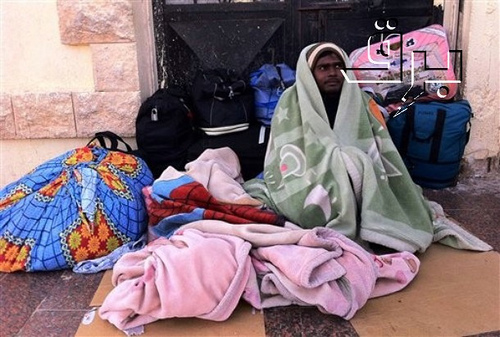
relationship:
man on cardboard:
[262, 40, 431, 257] [321, 210, 483, 336]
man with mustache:
[262, 40, 431, 257] [323, 74, 340, 84]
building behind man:
[0, 4, 499, 182] [262, 40, 431, 257]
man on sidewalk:
[262, 40, 431, 257] [2, 187, 496, 335]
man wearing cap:
[262, 40, 431, 257] [304, 44, 349, 72]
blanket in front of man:
[99, 217, 420, 335] [262, 40, 431, 257]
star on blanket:
[272, 105, 291, 125] [241, 41, 496, 262]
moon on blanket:
[301, 185, 334, 223] [241, 41, 496, 262]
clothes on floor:
[72, 237, 148, 276] [2, 260, 104, 336]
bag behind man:
[133, 88, 193, 160] [262, 40, 431, 257]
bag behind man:
[249, 62, 297, 126] [262, 40, 431, 257]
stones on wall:
[57, 5, 141, 143] [1, 0, 152, 187]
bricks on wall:
[0, 90, 146, 138] [1, 0, 152, 187]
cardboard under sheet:
[70, 255, 265, 335] [80, 149, 422, 334]